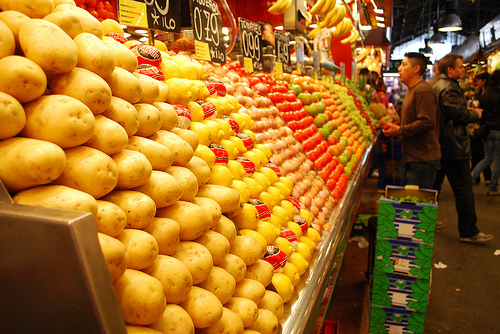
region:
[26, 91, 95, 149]
a golden yellow potato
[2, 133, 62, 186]
a golden yellow potato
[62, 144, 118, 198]
a golden yellow potato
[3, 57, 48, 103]
a golden yellow potato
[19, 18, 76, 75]
a golden yellow potato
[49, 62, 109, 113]
a golden yellow potato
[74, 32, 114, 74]
a golden yellow potato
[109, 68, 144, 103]
a golden yellow potato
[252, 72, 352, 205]
a section of red tomatoes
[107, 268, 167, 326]
a golden yellow potato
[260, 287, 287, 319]
a golden yellow potato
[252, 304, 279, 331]
a golden yellow potato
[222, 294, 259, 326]
a golden yellow potato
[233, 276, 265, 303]
a golden yellow potato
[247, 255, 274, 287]
a golden yellow potato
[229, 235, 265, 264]
a golden yellow potato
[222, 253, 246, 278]
a golden yellow potato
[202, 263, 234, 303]
a golden yellow potato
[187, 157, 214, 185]
a golden yellow potato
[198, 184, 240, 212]
a golden yellow potato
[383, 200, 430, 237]
Green boxes full of food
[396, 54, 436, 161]
Man looking at food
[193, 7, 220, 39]
Price of the food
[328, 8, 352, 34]
Bananas hanging above other fruit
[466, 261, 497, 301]
The ground is brown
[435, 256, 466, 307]
Trash on the ground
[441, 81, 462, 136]
Black leather coat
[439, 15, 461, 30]
Circular lamp in the store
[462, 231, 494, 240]
Gray shoes with white shoelaces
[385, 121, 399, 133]
Left hand of man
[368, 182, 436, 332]
four green boxes in front of the vegetable stand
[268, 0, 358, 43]
yellow bunches of bananas hanging above the vegetable stand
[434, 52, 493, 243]
a man in a black leather jacket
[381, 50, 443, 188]
a man in a brown shirt holding a red pepper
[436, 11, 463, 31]
dark light lights the walkway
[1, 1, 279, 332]
white potatoes stacked in the stand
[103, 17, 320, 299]
lemons stacked in the vegetable stand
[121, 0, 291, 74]
four signs above the stand of vegetables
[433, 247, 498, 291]
3 pieces of trash on the sidewalk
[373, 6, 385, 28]
three lights on the eave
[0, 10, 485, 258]
Vegetables and fruits market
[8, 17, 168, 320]
Nicely arranged potatoes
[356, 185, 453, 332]
A stack of reen cardboard boxes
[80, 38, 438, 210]
A man standing near vegetable store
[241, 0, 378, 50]
Bananas hanging on the top of the store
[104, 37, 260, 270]
Lemons besides potatoes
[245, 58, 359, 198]
Red tomatoes in the middle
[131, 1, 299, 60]
Signs on the top showing prices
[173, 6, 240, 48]
0.79 written on the board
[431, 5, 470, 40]
A light hanging from the ceiling